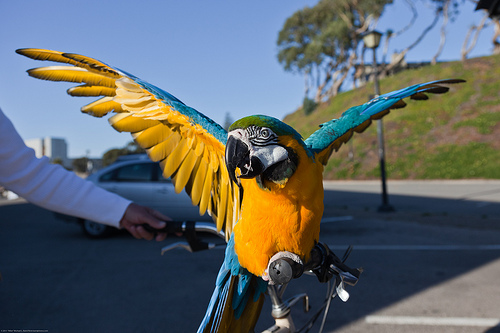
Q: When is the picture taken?
A: Day time.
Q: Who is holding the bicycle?
A: A person.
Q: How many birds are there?
A: One.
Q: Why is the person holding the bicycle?
A: Stablilize.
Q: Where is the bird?
A: On handlebars.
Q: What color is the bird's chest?
A: Yellow.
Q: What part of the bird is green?
A: Head.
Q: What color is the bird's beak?
A: Black.